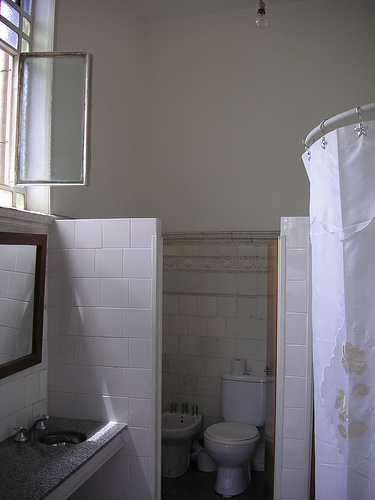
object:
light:
[254, 0, 269, 31]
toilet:
[202, 368, 274, 496]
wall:
[51, 0, 374, 474]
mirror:
[0, 232, 48, 379]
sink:
[0, 415, 128, 500]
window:
[13, 50, 93, 187]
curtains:
[299, 120, 375, 499]